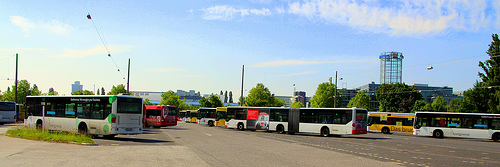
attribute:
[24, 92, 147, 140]
bus — parked, white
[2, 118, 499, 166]
lot — parking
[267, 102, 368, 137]
bus — parked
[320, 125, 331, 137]
wheel — tire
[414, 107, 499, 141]
bus — parked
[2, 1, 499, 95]
sky — blue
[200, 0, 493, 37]
cloud — wispy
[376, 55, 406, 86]
building — tall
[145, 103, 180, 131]
bus — red, parked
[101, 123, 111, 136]
marking — green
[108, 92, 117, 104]
marking — green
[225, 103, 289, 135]
bus — white, parked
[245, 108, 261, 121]
panel — red, advertising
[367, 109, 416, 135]
bus — yellow, parked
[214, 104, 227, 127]
bus — parked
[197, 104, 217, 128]
bus — parked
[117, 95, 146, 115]
window — back